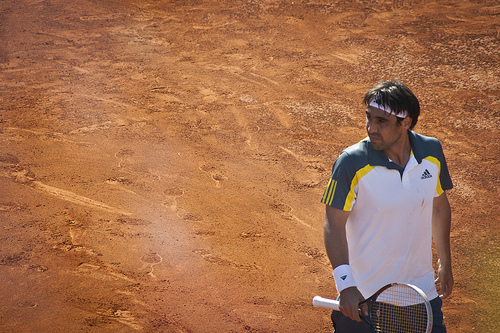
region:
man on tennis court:
[3, 2, 498, 329]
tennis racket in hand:
[312, 282, 434, 330]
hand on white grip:
[312, 287, 367, 322]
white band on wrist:
[332, 264, 364, 324]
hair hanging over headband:
[362, 81, 418, 118]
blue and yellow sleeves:
[321, 133, 452, 209]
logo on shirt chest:
[417, 168, 433, 180]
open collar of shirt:
[363, 132, 422, 187]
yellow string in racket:
[375, 288, 426, 330]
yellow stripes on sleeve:
[320, 173, 340, 205]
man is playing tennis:
[274, 49, 462, 319]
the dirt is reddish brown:
[33, 37, 276, 277]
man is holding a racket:
[284, 217, 462, 332]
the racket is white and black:
[275, 277, 440, 327]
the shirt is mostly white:
[310, 117, 459, 306]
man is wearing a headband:
[348, 74, 415, 128]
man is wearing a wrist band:
[313, 248, 367, 301]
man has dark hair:
[342, 60, 435, 133]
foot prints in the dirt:
[118, 123, 280, 306]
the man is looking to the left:
[325, 58, 432, 155]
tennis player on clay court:
[263, 79, 488, 331]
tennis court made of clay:
[113, 135, 221, 289]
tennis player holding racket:
[317, 69, 460, 331]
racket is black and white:
[273, 265, 453, 331]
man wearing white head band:
[355, 62, 422, 126]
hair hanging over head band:
[364, 69, 421, 159]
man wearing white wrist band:
[311, 253, 359, 307]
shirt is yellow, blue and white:
[325, 70, 471, 305]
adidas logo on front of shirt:
[415, 165, 435, 186]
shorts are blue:
[324, 282, 462, 332]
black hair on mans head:
[381, 89, 403, 99]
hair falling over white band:
[370, 96, 397, 109]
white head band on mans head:
[374, 105, 386, 110]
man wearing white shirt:
[376, 201, 393, 236]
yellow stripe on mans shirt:
[354, 164, 361, 195]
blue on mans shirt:
[337, 161, 351, 173]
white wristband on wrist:
[333, 262, 355, 289]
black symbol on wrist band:
[338, 271, 350, 283]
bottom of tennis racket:
[302, 287, 339, 317]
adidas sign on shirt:
[421, 163, 433, 188]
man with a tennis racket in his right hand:
[299, 102, 487, 307]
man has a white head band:
[363, 80, 419, 150]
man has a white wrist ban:
[318, 255, 361, 303]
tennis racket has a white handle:
[294, 277, 429, 327]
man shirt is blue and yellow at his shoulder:
[293, 133, 450, 220]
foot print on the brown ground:
[168, 129, 349, 308]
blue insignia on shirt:
[401, 155, 441, 209]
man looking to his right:
[288, 87, 453, 162]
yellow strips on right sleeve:
[313, 174, 368, 211]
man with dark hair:
[356, 78, 434, 129]